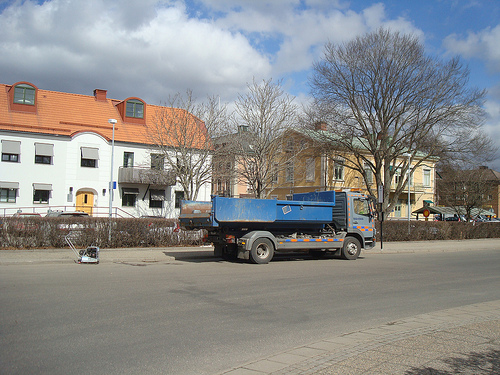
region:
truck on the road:
[166, 178, 397, 270]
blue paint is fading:
[231, 199, 258, 218]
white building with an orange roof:
[0, 80, 225, 228]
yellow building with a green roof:
[212, 105, 441, 222]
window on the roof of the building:
[116, 95, 152, 126]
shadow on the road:
[404, 351, 499, 373]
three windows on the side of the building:
[0, 134, 111, 173]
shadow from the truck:
[158, 240, 365, 265]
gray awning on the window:
[78, 143, 105, 168]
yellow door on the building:
[71, 188, 102, 220]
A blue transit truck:
[177, 187, 379, 264]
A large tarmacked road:
[0, 239, 499, 374]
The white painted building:
[0, 84, 212, 249]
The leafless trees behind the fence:
[126, 28, 491, 244]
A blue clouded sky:
[0, 0, 498, 165]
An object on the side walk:
[79, 245, 101, 264]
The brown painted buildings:
[216, 123, 440, 226]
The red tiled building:
[0, 75, 217, 227]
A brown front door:
[76, 185, 99, 220]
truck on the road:
[163, 178, 385, 273]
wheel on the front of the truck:
[339, 235, 366, 262]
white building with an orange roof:
[0, 76, 234, 232]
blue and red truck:
[180, 172, 396, 277]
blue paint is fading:
[226, 199, 256, 218]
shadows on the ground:
[406, 348, 498, 373]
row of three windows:
[0, 135, 107, 172]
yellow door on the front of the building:
[72, 184, 100, 218]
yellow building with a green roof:
[261, 111, 444, 226]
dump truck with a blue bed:
[170, 183, 377, 261]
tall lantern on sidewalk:
[102, 115, 126, 249]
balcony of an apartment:
[112, 162, 177, 187]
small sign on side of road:
[372, 177, 387, 251]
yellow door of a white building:
[74, 185, 101, 220]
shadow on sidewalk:
[402, 339, 494, 374]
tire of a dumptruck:
[248, 237, 277, 264]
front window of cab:
[352, 191, 373, 221]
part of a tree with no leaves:
[317, 40, 475, 172]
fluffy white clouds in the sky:
[110, 6, 341, 118]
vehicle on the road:
[189, 173, 384, 259]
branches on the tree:
[355, 58, 433, 97]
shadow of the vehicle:
[179, 246, 232, 258]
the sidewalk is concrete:
[338, 338, 371, 355]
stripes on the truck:
[290, 233, 319, 245]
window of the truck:
[346, 192, 373, 214]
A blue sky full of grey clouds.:
[0, 1, 499, 164]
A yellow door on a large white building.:
[74, 190, 93, 214]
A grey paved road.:
[1, 241, 498, 373]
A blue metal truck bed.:
[177, 191, 337, 228]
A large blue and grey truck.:
[180, 188, 377, 263]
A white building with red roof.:
[0, 81, 212, 216]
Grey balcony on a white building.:
[118, 165, 176, 185]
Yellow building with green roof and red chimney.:
[255, 120, 440, 222]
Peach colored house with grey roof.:
[208, 124, 262, 197]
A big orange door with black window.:
[75, 192, 94, 215]